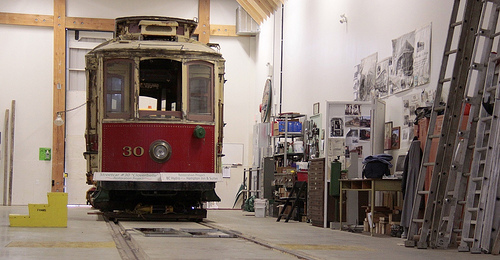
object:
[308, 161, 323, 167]
drawer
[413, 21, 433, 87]
posters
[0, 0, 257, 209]
wall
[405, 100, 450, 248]
ladder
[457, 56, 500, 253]
ladder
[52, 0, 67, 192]
beams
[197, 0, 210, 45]
beams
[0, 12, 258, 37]
beams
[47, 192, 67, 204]
stair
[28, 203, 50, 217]
stair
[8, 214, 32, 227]
yellow steps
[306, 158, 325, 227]
tool cabinet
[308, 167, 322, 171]
drawers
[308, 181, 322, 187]
drawers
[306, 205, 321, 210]
drawers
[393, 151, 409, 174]
computer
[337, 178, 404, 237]
workbench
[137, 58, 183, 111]
window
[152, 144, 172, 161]
headlight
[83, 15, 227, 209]
train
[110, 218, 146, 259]
tracks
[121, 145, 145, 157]
30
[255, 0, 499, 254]
wall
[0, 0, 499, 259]
garage